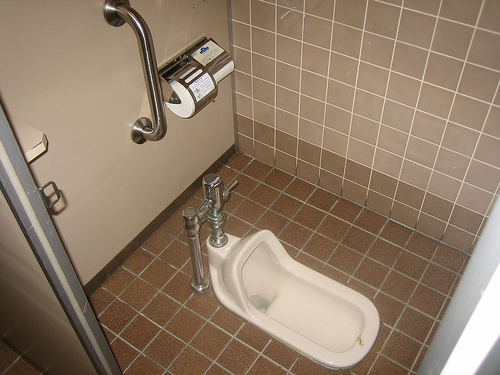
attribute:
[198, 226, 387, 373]
urinal — squat, japanese toilet